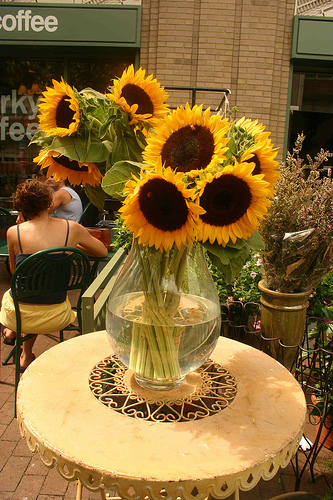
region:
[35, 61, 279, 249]
some large cut sunflowers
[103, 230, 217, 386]
the clear vase holding sunflowers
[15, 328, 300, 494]
metal table the vase is on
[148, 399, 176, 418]
part of the heart design on the inner circle of table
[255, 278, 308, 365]
a tall brown vase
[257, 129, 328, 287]
the flowers in the tall brown vase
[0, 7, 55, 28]
white letters on green sign above a shop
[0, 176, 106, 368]
a woman sitting in a green chair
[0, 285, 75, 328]
a yellow skirt the woman is wearing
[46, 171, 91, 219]
man in blue shirt sitting by the shop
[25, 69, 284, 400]
this is a flower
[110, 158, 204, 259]
this is a flower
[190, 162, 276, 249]
this is a flower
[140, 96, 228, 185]
this is a flower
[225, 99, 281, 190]
this is a flower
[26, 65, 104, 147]
this is a flower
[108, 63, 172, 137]
this is a flower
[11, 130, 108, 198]
this is a flower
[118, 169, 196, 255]
flower in a vase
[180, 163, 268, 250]
flower in a vase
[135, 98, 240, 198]
flower in a vase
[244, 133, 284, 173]
flower in a vase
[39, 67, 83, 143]
flower in a vase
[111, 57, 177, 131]
flower in a vase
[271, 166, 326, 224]
flower in a vase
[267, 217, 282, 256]
flower in a vase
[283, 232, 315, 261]
flower in a vase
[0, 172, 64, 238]
head of a person